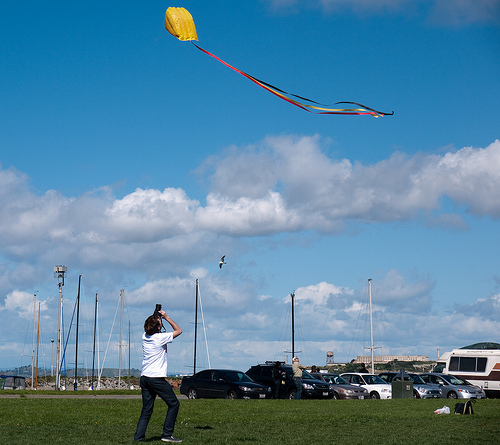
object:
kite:
[163, 3, 402, 120]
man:
[132, 307, 184, 445]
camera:
[151, 302, 163, 320]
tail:
[192, 45, 393, 120]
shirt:
[139, 329, 174, 381]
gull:
[217, 253, 228, 270]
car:
[178, 366, 273, 399]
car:
[329, 371, 392, 400]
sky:
[1, 1, 500, 377]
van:
[245, 364, 335, 400]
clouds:
[192, 186, 312, 239]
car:
[410, 371, 486, 399]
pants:
[132, 375, 180, 440]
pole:
[369, 276, 374, 376]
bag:
[453, 400, 473, 415]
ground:
[1, 388, 500, 444]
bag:
[432, 404, 452, 417]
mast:
[30, 295, 40, 389]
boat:
[1, 373, 30, 389]